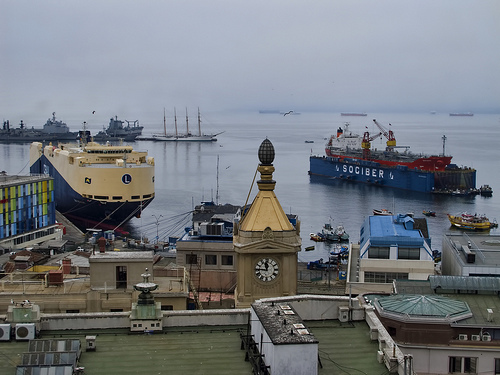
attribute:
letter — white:
[341, 162, 350, 174]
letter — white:
[361, 164, 372, 178]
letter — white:
[375, 168, 385, 180]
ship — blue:
[295, 110, 496, 218]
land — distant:
[221, 105, 498, 117]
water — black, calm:
[167, 153, 198, 191]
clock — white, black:
[252, 255, 282, 287]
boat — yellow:
[444, 210, 498, 232]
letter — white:
[364, 168, 371, 176]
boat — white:
[138, 89, 229, 153]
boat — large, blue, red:
[298, 120, 489, 205]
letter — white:
[340, 165, 385, 180]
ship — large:
[306, 115, 483, 201]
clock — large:
[247, 251, 283, 285]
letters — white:
[337, 161, 386, 178]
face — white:
[250, 256, 280, 284]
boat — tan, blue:
[25, 136, 156, 236]